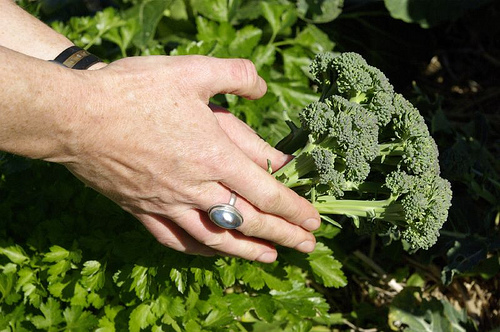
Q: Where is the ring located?
A: On woman's right hand.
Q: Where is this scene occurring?
A: In a garden.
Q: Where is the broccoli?
A: In woman's hands.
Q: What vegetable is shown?
A: Broccoli.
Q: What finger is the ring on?
A: Index Finger.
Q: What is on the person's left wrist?
A: A bracelet.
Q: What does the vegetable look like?
A: A tree.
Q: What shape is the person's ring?
A: An oval.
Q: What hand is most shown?
A: Right hand.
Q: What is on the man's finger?
A: Ring.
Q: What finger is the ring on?
A: Middle.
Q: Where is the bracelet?
A: On the wrist.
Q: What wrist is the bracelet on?
A: Left.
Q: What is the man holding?
A: Broccoli.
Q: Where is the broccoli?
A: Man's hand.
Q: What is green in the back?
A: Leaves.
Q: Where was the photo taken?
A: The garden.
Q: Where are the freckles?
A: Hands and arms.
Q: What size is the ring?
A: Medium.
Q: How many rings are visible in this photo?
A: One.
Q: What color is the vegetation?
A: Green.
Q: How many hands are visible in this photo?
A: Two.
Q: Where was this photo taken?
A: A vegetable garden.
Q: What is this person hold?
A: A stalk of broccoli.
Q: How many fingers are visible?
A: Six.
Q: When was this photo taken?
A: Outside, during the daytime.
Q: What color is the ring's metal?
A: Silver.